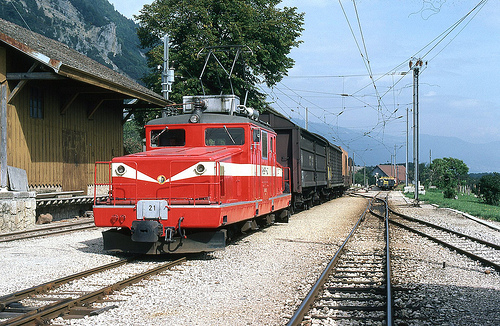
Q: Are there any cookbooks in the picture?
A: No, there are no cookbooks.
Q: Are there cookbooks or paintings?
A: No, there are no cookbooks or paintings.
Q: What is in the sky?
A: The clouds are in the sky.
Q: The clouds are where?
A: The clouds are in the sky.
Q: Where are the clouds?
A: The clouds are in the sky.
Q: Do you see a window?
A: Yes, there is a window.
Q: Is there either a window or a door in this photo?
A: Yes, there is a window.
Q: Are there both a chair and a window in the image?
A: No, there is a window but no chairs.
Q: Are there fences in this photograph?
A: No, there are no fences.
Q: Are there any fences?
A: No, there are no fences.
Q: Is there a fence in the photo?
A: No, there are no fences.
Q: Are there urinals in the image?
A: No, there are no urinals.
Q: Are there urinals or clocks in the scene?
A: No, there are no urinals or clocks.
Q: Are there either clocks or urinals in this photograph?
A: No, there are no urinals or clocks.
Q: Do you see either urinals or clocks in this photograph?
A: No, there are no urinals or clocks.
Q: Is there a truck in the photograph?
A: No, there are no trucks.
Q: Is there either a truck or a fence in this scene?
A: No, there are no trucks or fences.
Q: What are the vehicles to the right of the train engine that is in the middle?
A: The vehicles are cars.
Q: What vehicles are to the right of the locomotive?
A: The vehicles are cars.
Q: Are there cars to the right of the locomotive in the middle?
A: Yes, there are cars to the right of the locomotive.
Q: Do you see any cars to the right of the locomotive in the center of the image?
A: Yes, there are cars to the right of the locomotive.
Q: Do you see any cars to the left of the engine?
A: No, the cars are to the right of the engine.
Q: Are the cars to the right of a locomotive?
A: Yes, the cars are to the right of a locomotive.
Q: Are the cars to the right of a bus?
A: No, the cars are to the right of a locomotive.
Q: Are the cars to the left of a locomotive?
A: No, the cars are to the right of a locomotive.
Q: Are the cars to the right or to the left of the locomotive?
A: The cars are to the right of the locomotive.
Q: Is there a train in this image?
A: Yes, there is a train.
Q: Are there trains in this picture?
A: Yes, there is a train.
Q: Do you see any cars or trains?
A: Yes, there is a train.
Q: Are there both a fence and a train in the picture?
A: No, there is a train but no fences.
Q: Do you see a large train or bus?
A: Yes, there is a large train.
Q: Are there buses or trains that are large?
A: Yes, the train is large.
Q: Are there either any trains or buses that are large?
A: Yes, the train is large.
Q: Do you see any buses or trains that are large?
A: Yes, the train is large.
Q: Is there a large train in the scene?
A: Yes, there is a large train.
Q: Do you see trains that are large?
A: Yes, there is a train that is large.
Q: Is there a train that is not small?
A: Yes, there is a large train.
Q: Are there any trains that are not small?
A: Yes, there is a large train.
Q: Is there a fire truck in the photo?
A: No, there are no fire trucks.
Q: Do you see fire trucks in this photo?
A: No, there are no fire trucks.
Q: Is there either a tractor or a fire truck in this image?
A: No, there are no fire trucks or tractors.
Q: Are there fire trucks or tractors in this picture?
A: No, there are no fire trucks or tractors.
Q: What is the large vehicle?
A: The vehicle is a train.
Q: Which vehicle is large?
A: The vehicle is a train.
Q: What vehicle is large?
A: The vehicle is a train.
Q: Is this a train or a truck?
A: This is a train.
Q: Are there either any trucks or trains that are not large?
A: No, there is a train but it is large.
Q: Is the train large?
A: Yes, the train is large.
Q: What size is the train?
A: The train is large.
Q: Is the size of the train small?
A: No, the train is large.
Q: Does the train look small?
A: No, the train is large.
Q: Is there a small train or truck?
A: No, there is a train but it is large.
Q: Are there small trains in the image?
A: No, there is a train but it is large.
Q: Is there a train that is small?
A: No, there is a train but it is large.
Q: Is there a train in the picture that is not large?
A: No, there is a train but it is large.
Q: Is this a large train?
A: Yes, this is a large train.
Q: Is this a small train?
A: No, this is a large train.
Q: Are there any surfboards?
A: No, there are no surfboards.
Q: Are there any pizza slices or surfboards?
A: No, there are no surfboards or pizza slices.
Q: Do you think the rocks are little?
A: Yes, the rocks are little.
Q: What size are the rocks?
A: The rocks are little.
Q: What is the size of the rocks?
A: The rocks are little.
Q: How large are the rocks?
A: The rocks are little.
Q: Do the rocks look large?
A: No, the rocks are little.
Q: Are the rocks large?
A: No, the rocks are little.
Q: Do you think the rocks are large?
A: No, the rocks are little.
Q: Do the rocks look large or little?
A: The rocks are little.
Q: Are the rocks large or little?
A: The rocks are little.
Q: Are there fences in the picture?
A: No, there are no fences.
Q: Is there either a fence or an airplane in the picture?
A: No, there are no fences or airplanes.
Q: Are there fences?
A: No, there are no fences.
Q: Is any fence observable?
A: No, there are no fences.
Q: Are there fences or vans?
A: No, there are no fences or vans.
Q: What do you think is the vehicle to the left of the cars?
A: The vehicle is a locomotive.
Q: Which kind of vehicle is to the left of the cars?
A: The vehicle is a locomotive.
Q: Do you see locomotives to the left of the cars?
A: Yes, there is a locomotive to the left of the cars.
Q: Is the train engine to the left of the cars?
A: Yes, the train engine is to the left of the cars.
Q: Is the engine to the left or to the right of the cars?
A: The engine is to the left of the cars.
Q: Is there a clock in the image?
A: No, there are no clocks.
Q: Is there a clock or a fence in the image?
A: No, there are no clocks or fences.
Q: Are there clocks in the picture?
A: No, there are no clocks.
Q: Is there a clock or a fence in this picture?
A: No, there are no clocks or fences.